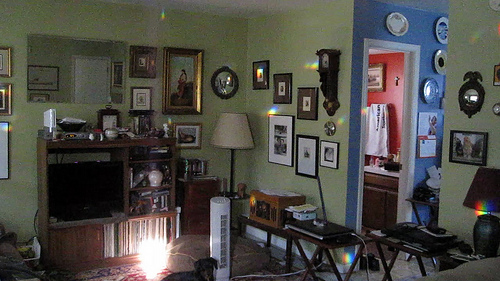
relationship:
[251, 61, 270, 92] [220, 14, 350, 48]
picture on wall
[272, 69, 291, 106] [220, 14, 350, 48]
picture on a wall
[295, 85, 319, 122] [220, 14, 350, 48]
picture on wall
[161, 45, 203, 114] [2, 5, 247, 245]
picture on wall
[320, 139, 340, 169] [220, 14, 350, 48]
picture on a wall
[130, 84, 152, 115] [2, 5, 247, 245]
picture on a wall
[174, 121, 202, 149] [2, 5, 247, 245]
picture on wall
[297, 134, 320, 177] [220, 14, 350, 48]
picture on a wall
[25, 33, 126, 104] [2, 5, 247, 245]
mirror on a wall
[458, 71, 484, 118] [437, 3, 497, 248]
mirror on a wall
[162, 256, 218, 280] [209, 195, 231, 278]
dog in front of air filter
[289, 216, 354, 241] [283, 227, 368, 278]
laptop on a tv stand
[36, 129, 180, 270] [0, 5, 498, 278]
entertainment center in living room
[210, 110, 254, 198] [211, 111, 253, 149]
lamp has a lampshade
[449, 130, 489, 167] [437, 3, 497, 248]
picture on wall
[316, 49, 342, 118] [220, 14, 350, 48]
clock on wall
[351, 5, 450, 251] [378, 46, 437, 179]
entrance to kitchen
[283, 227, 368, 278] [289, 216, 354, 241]
tv stand with a laptop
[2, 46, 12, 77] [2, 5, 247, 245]
painting on wall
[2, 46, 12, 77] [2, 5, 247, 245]
painting on a wall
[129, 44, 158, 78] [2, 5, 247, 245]
picture hangs on wall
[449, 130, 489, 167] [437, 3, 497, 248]
picture hanging on wall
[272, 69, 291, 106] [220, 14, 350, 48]
picture hangs on a wall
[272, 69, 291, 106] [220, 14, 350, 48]
picture on wall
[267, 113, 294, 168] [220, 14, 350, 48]
picture on wall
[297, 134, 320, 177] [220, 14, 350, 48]
picture on wall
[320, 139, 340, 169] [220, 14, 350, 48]
picture on wall